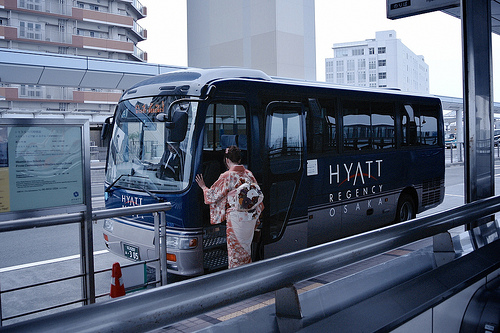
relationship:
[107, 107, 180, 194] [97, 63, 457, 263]
windshield on bus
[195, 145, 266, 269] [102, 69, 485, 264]
lady entering bus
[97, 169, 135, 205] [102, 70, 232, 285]
windshield wiper on window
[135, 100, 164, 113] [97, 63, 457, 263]
digital sign of bus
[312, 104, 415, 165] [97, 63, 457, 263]
window on side of bus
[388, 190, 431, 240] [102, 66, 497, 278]
tire on back of bus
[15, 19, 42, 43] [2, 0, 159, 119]
window on building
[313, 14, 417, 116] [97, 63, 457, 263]
building behind bus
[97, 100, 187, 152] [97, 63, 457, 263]
mirrors on bus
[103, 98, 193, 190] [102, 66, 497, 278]
window on bus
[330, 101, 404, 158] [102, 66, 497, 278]
window on bus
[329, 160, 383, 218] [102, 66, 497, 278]
hotel logo on bus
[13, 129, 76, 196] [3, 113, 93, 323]
information on stand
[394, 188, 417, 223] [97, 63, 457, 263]
tire on bus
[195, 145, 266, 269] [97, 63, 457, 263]
lady boarding bus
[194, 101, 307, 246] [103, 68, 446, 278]
bus door to van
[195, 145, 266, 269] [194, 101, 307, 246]
lady at bus door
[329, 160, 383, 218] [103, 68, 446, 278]
hotel logo on van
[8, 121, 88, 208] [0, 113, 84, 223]
signs under glass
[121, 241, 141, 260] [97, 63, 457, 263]
license plate on bus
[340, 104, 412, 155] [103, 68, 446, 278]
window of van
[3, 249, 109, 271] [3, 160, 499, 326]
line on road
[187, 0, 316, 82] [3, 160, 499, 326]
multi-storied building next to road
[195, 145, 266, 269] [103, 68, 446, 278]
lady entering into van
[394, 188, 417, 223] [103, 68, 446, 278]
tire of van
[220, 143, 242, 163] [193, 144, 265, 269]
hair of lady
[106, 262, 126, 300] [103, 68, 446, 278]
cone by van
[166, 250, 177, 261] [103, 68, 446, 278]
light on van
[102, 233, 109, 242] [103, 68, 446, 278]
light on van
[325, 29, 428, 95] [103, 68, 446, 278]
building above van